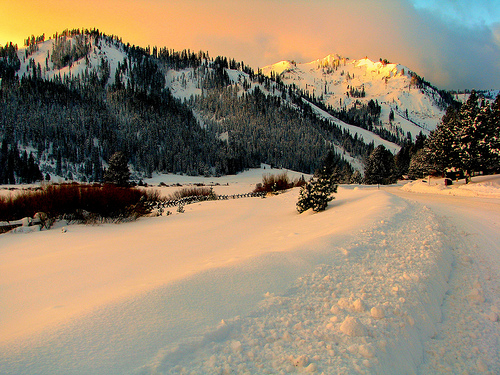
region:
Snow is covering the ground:
[0, 186, 495, 366]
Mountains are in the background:
[5, 23, 448, 181]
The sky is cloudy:
[3, 0, 499, 92]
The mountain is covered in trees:
[1, 30, 275, 181]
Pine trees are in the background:
[426, 83, 499, 186]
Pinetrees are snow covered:
[419, 90, 496, 177]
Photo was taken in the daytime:
[5, 7, 497, 359]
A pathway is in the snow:
[385, 178, 498, 373]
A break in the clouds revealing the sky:
[409, 3, 499, 43]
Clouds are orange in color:
[1, 1, 303, 52]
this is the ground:
[152, 242, 441, 371]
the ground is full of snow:
[223, 230, 393, 363]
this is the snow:
[196, 252, 256, 284]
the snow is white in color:
[183, 237, 255, 288]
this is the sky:
[262, 10, 464, 45]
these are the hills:
[34, 29, 450, 165]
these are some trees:
[113, 98, 285, 157]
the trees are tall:
[246, 97, 304, 164]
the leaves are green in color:
[138, 93, 172, 109]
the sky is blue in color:
[440, 8, 484, 18]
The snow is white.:
[265, 270, 403, 367]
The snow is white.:
[292, 248, 374, 350]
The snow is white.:
[324, 218, 435, 349]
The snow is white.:
[312, 300, 453, 370]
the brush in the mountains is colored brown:
[23, 187, 144, 222]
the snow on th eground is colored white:
[169, 265, 374, 332]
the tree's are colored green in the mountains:
[166, 96, 305, 157]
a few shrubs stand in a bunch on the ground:
[298, 165, 333, 214]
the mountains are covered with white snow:
[298, 59, 421, 113]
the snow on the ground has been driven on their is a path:
[443, 209, 494, 374]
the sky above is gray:
[416, 14, 492, 88]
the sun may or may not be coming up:
[119, 7, 331, 54]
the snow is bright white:
[14, 222, 211, 321]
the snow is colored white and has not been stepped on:
[10, 250, 183, 329]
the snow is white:
[153, 237, 266, 298]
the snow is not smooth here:
[286, 246, 436, 371]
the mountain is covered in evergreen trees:
[113, 106, 324, 176]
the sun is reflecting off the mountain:
[268, 48, 408, 93]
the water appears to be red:
[13, 173, 135, 229]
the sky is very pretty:
[54, 2, 215, 37]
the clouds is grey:
[439, 0, 491, 49]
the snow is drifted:
[82, 240, 387, 352]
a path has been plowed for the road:
[380, 191, 480, 296]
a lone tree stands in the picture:
[278, 167, 352, 224]